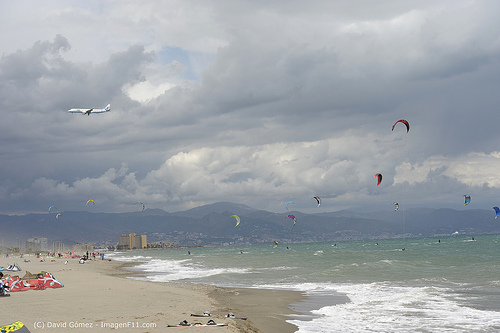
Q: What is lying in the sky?
A: Parasails.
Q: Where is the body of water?
A: The beach.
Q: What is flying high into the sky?
A: An airplane.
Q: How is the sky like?
A: Cloudy.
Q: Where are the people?
A: Beach.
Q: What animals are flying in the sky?
A: Birds.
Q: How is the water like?
A: Calm and uniform.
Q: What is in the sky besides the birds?
A: Kites.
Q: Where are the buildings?
A: Far from the beach.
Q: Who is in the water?
A: Several people.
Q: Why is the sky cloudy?
A: It is bound to rain.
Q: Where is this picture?
A: Beach.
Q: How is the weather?
A: Warm.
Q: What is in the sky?
A: Clouds.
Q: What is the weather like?
A: Cloudy.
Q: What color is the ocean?
A: Green.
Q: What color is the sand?
A: Tan.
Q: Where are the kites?
A: In the sky.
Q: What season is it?
A: Summer.